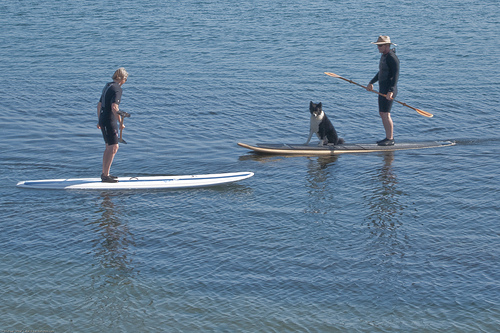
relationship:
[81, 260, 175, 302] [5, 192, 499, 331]
ripples in water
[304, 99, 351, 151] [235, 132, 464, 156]
dog on surfboard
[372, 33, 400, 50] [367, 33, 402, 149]
hat on man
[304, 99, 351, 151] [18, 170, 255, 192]
dog on surfboards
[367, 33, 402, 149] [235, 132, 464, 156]
man on surfboard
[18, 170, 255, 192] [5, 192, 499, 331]
surfboards in water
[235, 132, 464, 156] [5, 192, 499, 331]
surfboard in water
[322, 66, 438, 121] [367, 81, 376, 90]
paddle in hand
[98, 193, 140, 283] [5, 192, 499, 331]
reflection in water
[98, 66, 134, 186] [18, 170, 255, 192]
man on surfboards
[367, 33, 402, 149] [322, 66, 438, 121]
man holding paddle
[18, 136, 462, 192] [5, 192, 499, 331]
surfboards in water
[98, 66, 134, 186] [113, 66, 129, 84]
person has hair